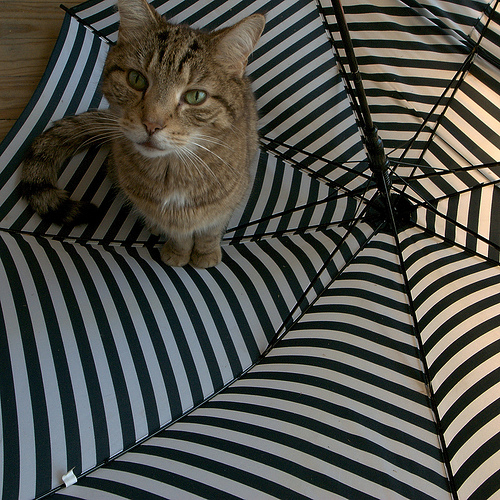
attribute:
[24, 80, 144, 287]
tail — black, brown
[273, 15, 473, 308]
umbrella — white, black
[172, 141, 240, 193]
whiskers — long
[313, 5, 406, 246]
metal pole — black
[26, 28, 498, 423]
umbrella — upside down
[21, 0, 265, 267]
cat — looking up, brown, black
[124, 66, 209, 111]
eyes — green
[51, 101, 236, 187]
white whiskers — long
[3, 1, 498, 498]
umbrella — black, white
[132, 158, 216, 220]
stripes — long, black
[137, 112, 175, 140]
nose — small